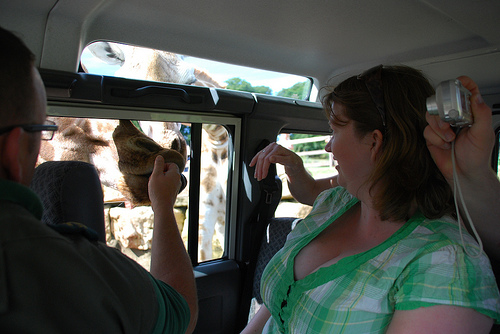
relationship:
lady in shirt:
[240, 64, 498, 334] [233, 167, 483, 332]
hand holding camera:
[423, 117, 490, 168] [420, 77, 475, 128]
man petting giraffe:
[12, 77, 93, 325] [81, 80, 208, 191]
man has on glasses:
[0, 27, 200, 334] [3, 117, 58, 139]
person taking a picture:
[433, 76, 498, 261] [9, 50, 474, 296]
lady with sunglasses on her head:
[235, 64, 499, 331] [316, 61, 444, 210]